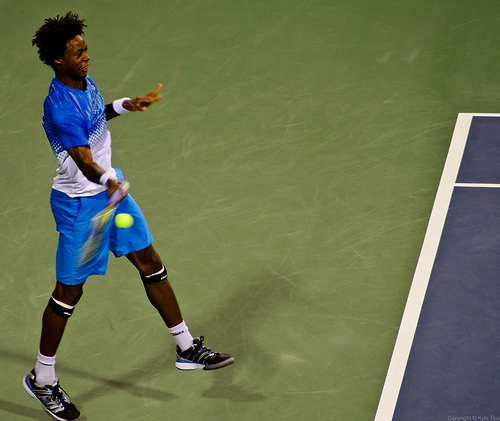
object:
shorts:
[45, 165, 158, 287]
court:
[2, 1, 494, 420]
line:
[374, 97, 472, 420]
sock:
[164, 317, 193, 349]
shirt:
[35, 71, 129, 198]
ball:
[112, 211, 134, 229]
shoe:
[172, 336, 236, 373]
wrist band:
[111, 96, 141, 117]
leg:
[118, 244, 185, 332]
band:
[140, 264, 167, 285]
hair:
[27, 10, 87, 66]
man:
[20, 10, 237, 420]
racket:
[78, 179, 131, 270]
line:
[437, 181, 498, 191]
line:
[451, 110, 499, 120]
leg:
[38, 240, 86, 361]